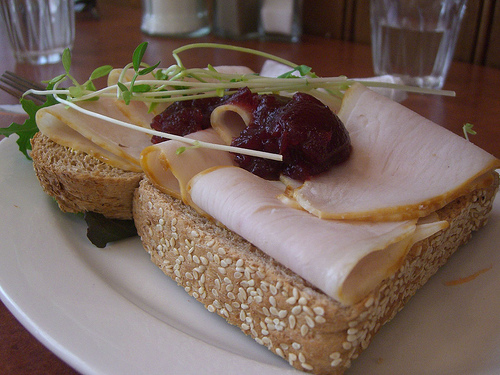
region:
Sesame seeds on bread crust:
[141, 198, 321, 374]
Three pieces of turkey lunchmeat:
[142, 83, 494, 304]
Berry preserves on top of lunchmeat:
[147, 90, 350, 179]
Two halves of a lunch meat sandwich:
[35, 62, 498, 373]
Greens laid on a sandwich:
[10, 42, 455, 168]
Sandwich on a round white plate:
[3, 97, 495, 372]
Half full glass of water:
[368, 1, 467, 89]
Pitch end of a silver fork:
[0, 66, 65, 106]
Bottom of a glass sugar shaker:
[137, 0, 212, 39]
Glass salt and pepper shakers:
[209, 0, 304, 42]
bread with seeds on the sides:
[161, 205, 253, 323]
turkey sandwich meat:
[282, 195, 399, 285]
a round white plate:
[16, 229, 140, 374]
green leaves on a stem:
[80, 45, 192, 109]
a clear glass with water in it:
[380, 6, 467, 101]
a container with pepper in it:
[206, 5, 254, 46]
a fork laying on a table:
[2, 63, 54, 114]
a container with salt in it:
[255, 11, 323, 51]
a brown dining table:
[86, 24, 171, 68]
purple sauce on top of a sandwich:
[238, 107, 345, 179]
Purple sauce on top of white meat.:
[256, 110, 333, 160]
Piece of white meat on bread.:
[211, 171, 353, 295]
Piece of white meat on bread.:
[326, 77, 471, 198]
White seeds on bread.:
[178, 237, 308, 342]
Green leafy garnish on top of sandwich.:
[42, 48, 326, 90]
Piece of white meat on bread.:
[60, 91, 138, 166]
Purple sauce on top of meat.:
[166, 83, 219, 130]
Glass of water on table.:
[355, 35, 453, 71]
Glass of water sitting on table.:
[16, 17, 80, 52]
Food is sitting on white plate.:
[88, 85, 393, 324]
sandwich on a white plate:
[3, 31, 493, 372]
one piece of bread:
[6, 15, 481, 367]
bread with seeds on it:
[22, 36, 497, 371]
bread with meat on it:
[6, 28, 498, 360]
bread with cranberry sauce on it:
[16, 70, 498, 372]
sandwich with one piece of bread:
[4, 29, 498, 374]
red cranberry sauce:
[159, 70, 352, 177]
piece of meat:
[226, 192, 421, 278]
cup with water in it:
[360, 3, 494, 93]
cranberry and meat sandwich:
[0, 39, 498, 373]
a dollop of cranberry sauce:
[144, 81, 351, 178]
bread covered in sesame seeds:
[131, 188, 498, 372]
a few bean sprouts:
[15, 43, 450, 103]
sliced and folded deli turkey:
[151, 82, 469, 290]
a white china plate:
[0, 133, 296, 373]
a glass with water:
[366, 5, 463, 83]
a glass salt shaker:
[258, 2, 303, 42]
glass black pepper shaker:
[215, 0, 256, 44]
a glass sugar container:
[140, 2, 206, 42]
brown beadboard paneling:
[309, 0, 496, 60]